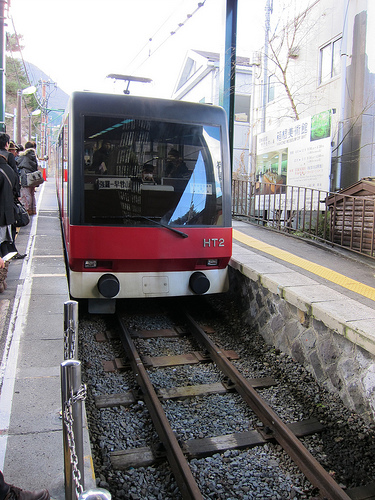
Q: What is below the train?
A: Tracks.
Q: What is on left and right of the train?
A: Platform.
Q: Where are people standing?
A: On left platform.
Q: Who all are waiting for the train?
A: People.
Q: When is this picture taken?
A: Daytime.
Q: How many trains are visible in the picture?
A: One.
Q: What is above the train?
A: Electric cables.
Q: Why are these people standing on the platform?
A: To board on the train.